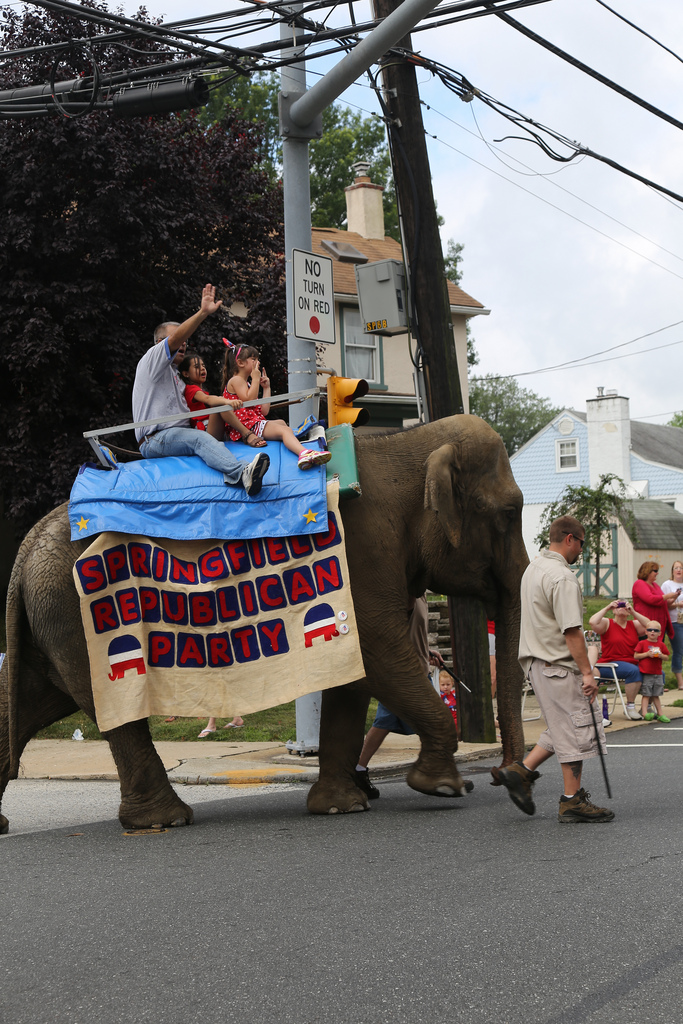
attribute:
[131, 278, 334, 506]
man/two kids — riding an elephant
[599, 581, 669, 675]
clothing — red